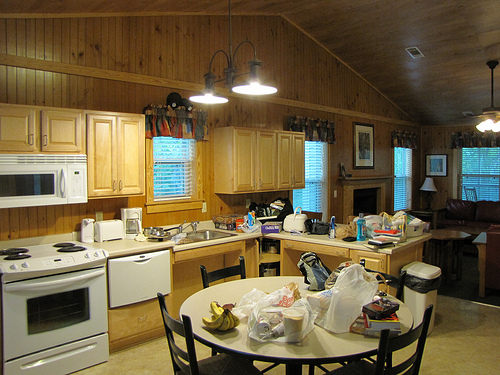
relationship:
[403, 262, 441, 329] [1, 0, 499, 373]
garbage can in kitchen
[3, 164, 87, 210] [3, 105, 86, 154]
microwave under cabinet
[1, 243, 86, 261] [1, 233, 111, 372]
burners on stove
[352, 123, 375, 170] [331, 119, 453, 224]
picture hanging on wall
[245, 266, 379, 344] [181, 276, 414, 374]
grocery bags on kitchen table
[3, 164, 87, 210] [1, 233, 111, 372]
microwave above stove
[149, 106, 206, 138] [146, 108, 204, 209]
valance on window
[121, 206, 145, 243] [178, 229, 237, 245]
coffee maker next to sink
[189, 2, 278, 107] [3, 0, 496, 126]
light fixtures on ceiling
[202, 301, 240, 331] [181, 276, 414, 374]
bunch of bananas on kitchen table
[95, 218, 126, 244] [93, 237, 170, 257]
toaster on counter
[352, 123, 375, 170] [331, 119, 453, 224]
picture on wall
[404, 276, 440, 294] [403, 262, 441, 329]
bag in garbage can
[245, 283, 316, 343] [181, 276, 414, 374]
plastic bag on kitchen table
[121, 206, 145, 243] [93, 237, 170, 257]
coffee maker on counter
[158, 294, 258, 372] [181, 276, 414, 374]
chair at kitchen table